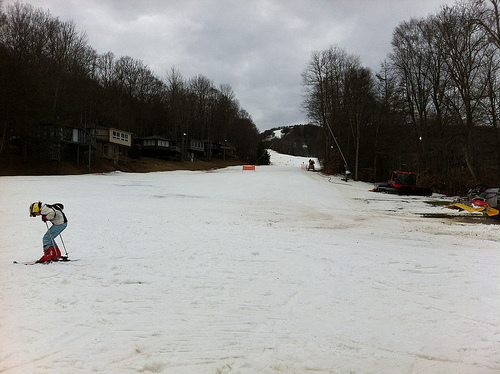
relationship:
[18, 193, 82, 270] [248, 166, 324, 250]
person on ground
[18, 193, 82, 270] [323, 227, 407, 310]
person in snow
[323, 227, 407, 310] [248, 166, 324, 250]
snow on ground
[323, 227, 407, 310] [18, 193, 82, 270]
snow near person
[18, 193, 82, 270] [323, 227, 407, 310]
person near snow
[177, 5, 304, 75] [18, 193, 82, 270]
sky above person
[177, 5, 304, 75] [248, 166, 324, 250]
sky above ground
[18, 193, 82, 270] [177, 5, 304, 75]
person below sky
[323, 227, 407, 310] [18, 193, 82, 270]
snow on person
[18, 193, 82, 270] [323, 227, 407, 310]
person by snow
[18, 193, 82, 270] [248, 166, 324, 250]
person by ground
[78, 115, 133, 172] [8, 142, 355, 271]
house near slope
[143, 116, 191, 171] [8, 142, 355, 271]
house near slope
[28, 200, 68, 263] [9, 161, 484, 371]
person skiing in snow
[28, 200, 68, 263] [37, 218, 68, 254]
person wearing pants